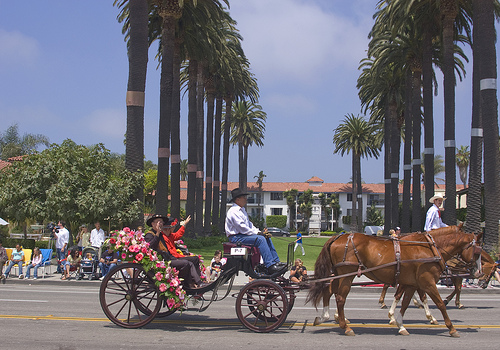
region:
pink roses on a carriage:
[108, 224, 173, 315]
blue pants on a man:
[229, 224, 287, 270]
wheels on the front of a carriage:
[230, 279, 296, 333]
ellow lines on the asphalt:
[28, 301, 95, 323]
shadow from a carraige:
[120, 295, 315, 330]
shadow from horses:
[313, 305, 463, 339]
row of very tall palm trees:
[323, 7, 498, 244]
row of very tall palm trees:
[116, 3, 272, 233]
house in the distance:
[236, 165, 423, 240]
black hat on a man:
[229, 181, 251, 208]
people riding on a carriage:
[110, 176, 287, 314]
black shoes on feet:
[271, 263, 288, 275]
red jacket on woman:
[166, 215, 190, 252]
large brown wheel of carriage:
[93, 263, 178, 335]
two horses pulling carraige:
[283, 220, 485, 348]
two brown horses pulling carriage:
[308, 227, 486, 333]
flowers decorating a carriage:
[115, 231, 182, 307]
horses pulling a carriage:
[330, 226, 498, 311]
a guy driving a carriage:
[213, 187, 308, 275]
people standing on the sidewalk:
[17, 227, 122, 290]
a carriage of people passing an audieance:
[120, 214, 482, 320]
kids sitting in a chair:
[13, 245, 43, 266]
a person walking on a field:
[281, 222, 312, 249]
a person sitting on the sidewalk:
[288, 248, 308, 281]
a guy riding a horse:
[413, 184, 496, 258]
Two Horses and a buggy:
[93, 188, 497, 332]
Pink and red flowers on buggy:
[101, 223, 186, 327]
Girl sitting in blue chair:
[27, 249, 51, 279]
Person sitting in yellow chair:
[3, 245, 29, 277]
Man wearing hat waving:
[142, 210, 169, 262]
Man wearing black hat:
[223, 185, 284, 273]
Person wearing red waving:
[160, 213, 199, 257]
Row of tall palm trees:
[113, 3, 261, 188]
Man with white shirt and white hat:
[423, 191, 451, 230]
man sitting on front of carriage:
[222, 178, 282, 280]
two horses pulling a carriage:
[324, 208, 479, 333]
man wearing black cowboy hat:
[225, 180, 287, 302]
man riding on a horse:
[418, 183, 465, 228]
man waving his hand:
[140, 210, 197, 282]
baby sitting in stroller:
[75, 233, 101, 277]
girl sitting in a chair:
[31, 243, 48, 272]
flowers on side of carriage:
[107, 220, 187, 305]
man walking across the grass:
[285, 226, 311, 251]